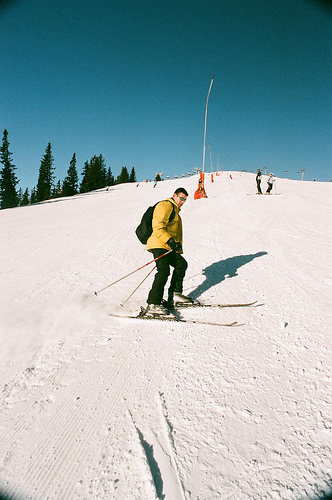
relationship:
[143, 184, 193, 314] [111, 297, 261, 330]
man wearing skis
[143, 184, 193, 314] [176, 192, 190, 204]
man wearing goggles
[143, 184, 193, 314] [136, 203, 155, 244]
skier wearing backpack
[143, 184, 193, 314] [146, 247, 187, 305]
skier wearing pants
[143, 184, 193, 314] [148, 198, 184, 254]
skier wearing jacket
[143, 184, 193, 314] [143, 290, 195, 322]
skier wearing boots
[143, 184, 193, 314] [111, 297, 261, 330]
skier wearing skis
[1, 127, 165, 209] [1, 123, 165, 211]
leaves on trees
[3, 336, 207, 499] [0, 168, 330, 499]
tracks in snow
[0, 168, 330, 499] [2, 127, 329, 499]
snow on mountain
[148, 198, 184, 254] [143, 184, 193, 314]
jacket on skier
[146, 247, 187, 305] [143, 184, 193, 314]
pants on skier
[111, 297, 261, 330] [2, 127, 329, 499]
pair of skis on mountain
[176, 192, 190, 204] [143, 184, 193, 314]
pair of sunglasses on skier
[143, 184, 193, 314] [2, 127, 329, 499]
man on mountain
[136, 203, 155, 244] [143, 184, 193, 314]
backpack on skier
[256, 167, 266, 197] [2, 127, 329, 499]
person standing on mountain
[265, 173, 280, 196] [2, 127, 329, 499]
person standing on mountain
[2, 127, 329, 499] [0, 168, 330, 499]
mountain covered in snow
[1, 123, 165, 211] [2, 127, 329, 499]
trees on mountain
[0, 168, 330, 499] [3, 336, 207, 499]
snow has tracks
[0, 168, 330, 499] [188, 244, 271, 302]
snow has a shadow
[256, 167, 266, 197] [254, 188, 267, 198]
person on skis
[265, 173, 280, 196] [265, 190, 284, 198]
person on skis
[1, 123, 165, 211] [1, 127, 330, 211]
trees in background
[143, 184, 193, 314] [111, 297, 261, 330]
man on skis